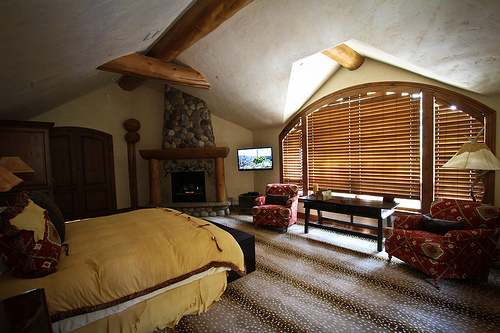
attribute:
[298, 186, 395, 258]
table — wooden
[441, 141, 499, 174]
lampshade — brown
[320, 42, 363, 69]
beam — wood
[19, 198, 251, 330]
bed — large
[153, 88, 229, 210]
fireplace — large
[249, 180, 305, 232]
sofa — red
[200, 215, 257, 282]
container — black, storage container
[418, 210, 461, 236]
pillow — dark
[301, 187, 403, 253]
table — black